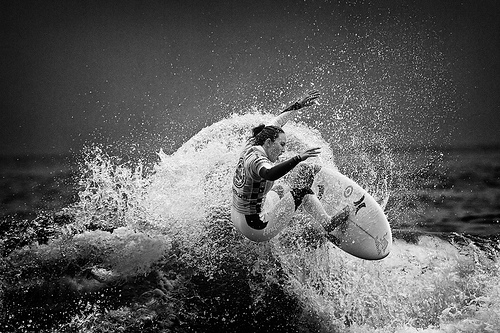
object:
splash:
[0, 107, 500, 333]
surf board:
[283, 165, 393, 260]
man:
[229, 91, 349, 241]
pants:
[230, 186, 335, 242]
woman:
[230, 89, 348, 241]